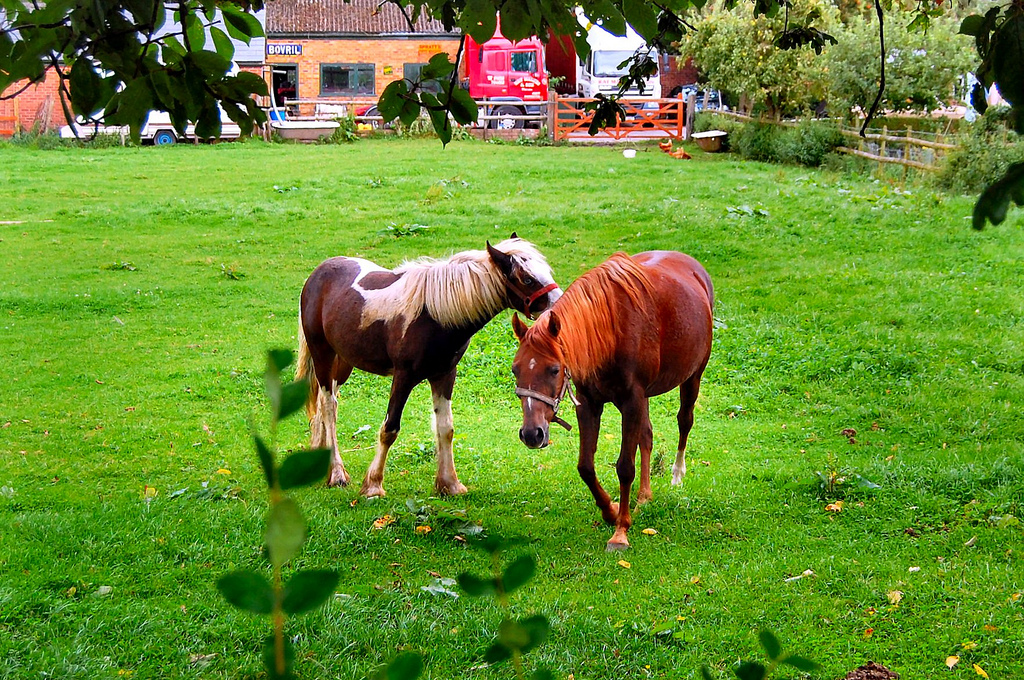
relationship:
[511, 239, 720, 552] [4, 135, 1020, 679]
horse stands on top of grass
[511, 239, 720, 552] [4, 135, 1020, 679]
horse in grass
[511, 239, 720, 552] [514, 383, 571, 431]
horse wearing bridle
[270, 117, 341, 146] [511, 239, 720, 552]
trough for horse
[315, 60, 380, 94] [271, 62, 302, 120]
window next to door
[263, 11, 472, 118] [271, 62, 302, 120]
building has door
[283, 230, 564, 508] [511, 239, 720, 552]
horse nudging horse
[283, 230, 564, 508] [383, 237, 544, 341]
horse has mane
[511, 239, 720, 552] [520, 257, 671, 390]
horse has mane